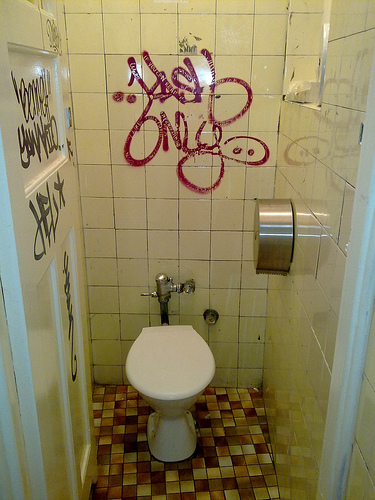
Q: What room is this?
A: Bathroom.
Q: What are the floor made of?
A: Tiles.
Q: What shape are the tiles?
A: Square.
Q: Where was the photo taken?
A: The bathroom.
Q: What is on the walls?
A: Graffiti.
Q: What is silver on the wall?
A: Toilet paper holder.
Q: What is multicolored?
A: Floor tiles.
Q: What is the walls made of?
A: Tiles.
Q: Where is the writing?
A: On the walls.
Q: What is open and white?
A: The door.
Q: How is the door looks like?
A: Dirty.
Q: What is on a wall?
A: Graffiti painted.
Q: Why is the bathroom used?
A: Toilet.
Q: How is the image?
A: Ugly.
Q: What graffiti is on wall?
A: Red.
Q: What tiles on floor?
A: Square.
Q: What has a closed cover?
A: Toilet.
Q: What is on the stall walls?
A: Graffiti.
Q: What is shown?
A: Bathroom stall.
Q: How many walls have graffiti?
A: 2.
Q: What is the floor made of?
A: Tile.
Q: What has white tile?
A: Back wall.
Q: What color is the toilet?
A: White.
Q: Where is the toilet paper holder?
A: Right wall.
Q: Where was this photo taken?
A: Restroom.